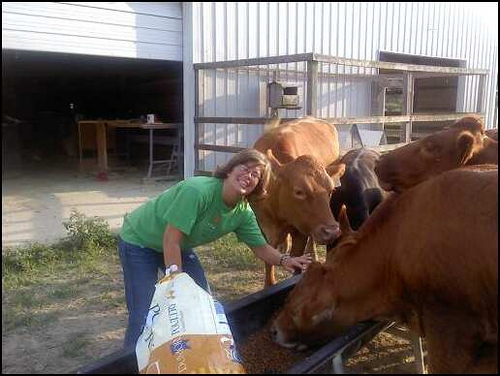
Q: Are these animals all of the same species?
A: Yes, all the animals are cows.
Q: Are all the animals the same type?
A: Yes, all the animals are cows.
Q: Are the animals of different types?
A: No, all the animals are cows.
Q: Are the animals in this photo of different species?
A: No, all the animals are cows.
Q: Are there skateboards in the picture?
A: No, there are no skateboards.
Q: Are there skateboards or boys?
A: No, there are no skateboards or boys.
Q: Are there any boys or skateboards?
A: No, there are no skateboards or boys.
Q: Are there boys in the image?
A: No, there are no boys.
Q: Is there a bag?
A: Yes, there is a bag.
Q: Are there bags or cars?
A: Yes, there is a bag.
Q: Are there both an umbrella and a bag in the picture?
A: No, there is a bag but no umbrellas.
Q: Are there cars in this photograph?
A: No, there are no cars.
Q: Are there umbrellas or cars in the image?
A: No, there are no cars or umbrellas.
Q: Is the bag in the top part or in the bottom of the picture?
A: The bag is in the bottom of the image.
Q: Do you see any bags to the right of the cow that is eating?
A: No, the bag is to the left of the cow.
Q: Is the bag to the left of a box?
A: No, the bag is to the left of the cow.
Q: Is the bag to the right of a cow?
A: No, the bag is to the left of a cow.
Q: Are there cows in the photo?
A: Yes, there is a cow.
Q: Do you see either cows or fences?
A: Yes, there is a cow.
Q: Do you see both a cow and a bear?
A: No, there is a cow but no bears.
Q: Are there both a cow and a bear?
A: No, there is a cow but no bears.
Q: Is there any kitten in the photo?
A: No, there are no kittens.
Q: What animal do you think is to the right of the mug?
A: The animal is a cow.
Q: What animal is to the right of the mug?
A: The animal is a cow.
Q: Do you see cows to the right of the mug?
A: Yes, there is a cow to the right of the mug.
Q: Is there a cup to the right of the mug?
A: No, there is a cow to the right of the mug.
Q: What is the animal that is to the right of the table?
A: The animal is a cow.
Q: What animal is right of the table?
A: The animal is a cow.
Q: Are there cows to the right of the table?
A: Yes, there is a cow to the right of the table.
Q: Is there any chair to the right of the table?
A: No, there is a cow to the right of the table.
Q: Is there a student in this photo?
A: No, there are no students.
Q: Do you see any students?
A: No, there are no students.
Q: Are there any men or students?
A: No, there are no students or men.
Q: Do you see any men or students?
A: No, there are no students or men.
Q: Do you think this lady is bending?
A: Yes, the lady is bending.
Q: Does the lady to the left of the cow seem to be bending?
A: Yes, the lady is bending.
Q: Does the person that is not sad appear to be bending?
A: Yes, the lady is bending.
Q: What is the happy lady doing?
A: The lady is bending.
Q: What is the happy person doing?
A: The lady is bending.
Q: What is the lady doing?
A: The lady is bending.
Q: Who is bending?
A: The lady is bending.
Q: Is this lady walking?
A: No, the lady is bending.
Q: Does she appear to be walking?
A: No, the lady is bending.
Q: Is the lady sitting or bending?
A: The lady is bending.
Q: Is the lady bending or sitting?
A: The lady is bending.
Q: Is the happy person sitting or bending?
A: The lady is bending.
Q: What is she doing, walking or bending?
A: The lady is bending.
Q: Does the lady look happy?
A: Yes, the lady is happy.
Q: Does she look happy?
A: Yes, the lady is happy.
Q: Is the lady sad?
A: No, the lady is happy.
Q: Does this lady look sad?
A: No, the lady is happy.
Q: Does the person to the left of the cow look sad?
A: No, the lady is happy.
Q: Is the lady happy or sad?
A: The lady is happy.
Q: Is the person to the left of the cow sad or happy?
A: The lady is happy.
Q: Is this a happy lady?
A: Yes, this is a happy lady.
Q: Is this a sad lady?
A: No, this is a happy lady.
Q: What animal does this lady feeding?
A: The lady feeding the cow.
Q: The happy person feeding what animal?
A: The lady feeding the cow.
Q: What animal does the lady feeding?
A: The lady feeding the cow.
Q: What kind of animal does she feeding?
A: The lady feeding the cow.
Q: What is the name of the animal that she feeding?
A: The animal is a cow.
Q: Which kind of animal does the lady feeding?
A: The lady feeding the cow.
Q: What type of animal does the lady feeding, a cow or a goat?
A: The lady feeding a cow.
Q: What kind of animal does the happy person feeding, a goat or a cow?
A: The lady feeding a cow.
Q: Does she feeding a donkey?
A: No, the lady feeding the cow.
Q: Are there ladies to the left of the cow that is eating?
A: Yes, there is a lady to the left of the cow.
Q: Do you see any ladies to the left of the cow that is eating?
A: Yes, there is a lady to the left of the cow.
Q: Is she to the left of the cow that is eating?
A: Yes, the lady is to the left of the cow.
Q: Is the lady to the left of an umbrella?
A: No, the lady is to the left of the cow.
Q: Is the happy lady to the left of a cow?
A: Yes, the lady is to the left of a cow.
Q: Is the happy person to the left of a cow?
A: Yes, the lady is to the left of a cow.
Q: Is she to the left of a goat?
A: No, the lady is to the left of a cow.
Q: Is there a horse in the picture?
A: No, there are no horses.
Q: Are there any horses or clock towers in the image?
A: No, there are no horses or clock towers.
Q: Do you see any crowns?
A: No, there are no crowns.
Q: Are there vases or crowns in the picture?
A: No, there are no crowns or vases.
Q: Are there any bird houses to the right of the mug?
A: Yes, there is a bird house to the right of the mug.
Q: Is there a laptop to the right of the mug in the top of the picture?
A: No, there is a bird house to the right of the mug.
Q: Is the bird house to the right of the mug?
A: Yes, the bird house is to the right of the mug.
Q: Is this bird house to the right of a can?
A: No, the bird house is to the right of the mug.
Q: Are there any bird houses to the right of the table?
A: Yes, there is a bird house to the right of the table.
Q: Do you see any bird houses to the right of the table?
A: Yes, there is a bird house to the right of the table.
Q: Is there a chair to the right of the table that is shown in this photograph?
A: No, there is a bird house to the right of the table.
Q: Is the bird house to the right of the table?
A: Yes, the bird house is to the right of the table.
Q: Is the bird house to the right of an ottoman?
A: No, the bird house is to the right of the table.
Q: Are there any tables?
A: Yes, there is a table.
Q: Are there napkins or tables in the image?
A: Yes, there is a table.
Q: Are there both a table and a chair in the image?
A: No, there is a table but no chairs.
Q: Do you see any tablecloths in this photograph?
A: No, there are no tablecloths.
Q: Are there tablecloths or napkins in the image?
A: No, there are no tablecloths or napkins.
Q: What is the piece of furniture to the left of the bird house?
A: The piece of furniture is a table.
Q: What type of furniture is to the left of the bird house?
A: The piece of furniture is a table.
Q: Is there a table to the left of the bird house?
A: Yes, there is a table to the left of the bird house.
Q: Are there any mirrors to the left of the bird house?
A: No, there is a table to the left of the bird house.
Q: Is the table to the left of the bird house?
A: Yes, the table is to the left of the bird house.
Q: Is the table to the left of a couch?
A: No, the table is to the left of the bird house.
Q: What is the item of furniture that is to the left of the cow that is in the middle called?
A: The piece of furniture is a table.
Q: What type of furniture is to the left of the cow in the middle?
A: The piece of furniture is a table.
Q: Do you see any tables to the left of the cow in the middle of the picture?
A: Yes, there is a table to the left of the cow.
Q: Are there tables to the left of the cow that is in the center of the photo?
A: Yes, there is a table to the left of the cow.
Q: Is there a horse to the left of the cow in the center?
A: No, there is a table to the left of the cow.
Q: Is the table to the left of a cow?
A: Yes, the table is to the left of a cow.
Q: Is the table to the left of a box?
A: No, the table is to the left of a cow.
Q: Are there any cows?
A: Yes, there is a cow.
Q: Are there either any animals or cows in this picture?
A: Yes, there is a cow.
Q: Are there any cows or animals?
A: Yes, there is a cow.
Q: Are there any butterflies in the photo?
A: No, there are no butterflies.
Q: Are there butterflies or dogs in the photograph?
A: No, there are no butterflies or dogs.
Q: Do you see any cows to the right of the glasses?
A: Yes, there is a cow to the right of the glasses.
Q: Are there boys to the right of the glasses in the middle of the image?
A: No, there is a cow to the right of the glasses.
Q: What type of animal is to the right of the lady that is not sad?
A: The animal is a cow.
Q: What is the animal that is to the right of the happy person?
A: The animal is a cow.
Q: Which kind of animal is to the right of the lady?
A: The animal is a cow.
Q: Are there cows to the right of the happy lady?
A: Yes, there is a cow to the right of the lady.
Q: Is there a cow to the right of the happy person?
A: Yes, there is a cow to the right of the lady.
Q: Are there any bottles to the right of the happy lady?
A: No, there is a cow to the right of the lady.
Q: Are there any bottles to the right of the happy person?
A: No, there is a cow to the right of the lady.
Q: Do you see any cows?
A: Yes, there is a cow.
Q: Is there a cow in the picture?
A: Yes, there is a cow.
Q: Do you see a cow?
A: Yes, there is a cow.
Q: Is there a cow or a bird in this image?
A: Yes, there is a cow.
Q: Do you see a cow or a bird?
A: Yes, there is a cow.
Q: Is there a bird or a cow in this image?
A: Yes, there is a cow.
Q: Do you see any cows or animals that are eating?
A: Yes, the cow is eating.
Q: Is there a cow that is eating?
A: Yes, there is a cow that is eating.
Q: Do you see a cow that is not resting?
A: Yes, there is a cow that is eating .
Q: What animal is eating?
A: The animal is a cow.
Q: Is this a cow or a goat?
A: This is a cow.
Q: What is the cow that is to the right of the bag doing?
A: The cow is eating.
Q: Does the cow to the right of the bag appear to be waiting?
A: No, the cow is eating.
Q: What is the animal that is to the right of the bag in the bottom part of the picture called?
A: The animal is a cow.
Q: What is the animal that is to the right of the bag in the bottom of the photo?
A: The animal is a cow.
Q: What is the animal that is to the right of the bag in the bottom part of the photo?
A: The animal is a cow.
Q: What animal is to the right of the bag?
A: The animal is a cow.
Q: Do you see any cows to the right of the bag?
A: Yes, there is a cow to the right of the bag.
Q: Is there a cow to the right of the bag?
A: Yes, there is a cow to the right of the bag.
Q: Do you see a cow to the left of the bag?
A: No, the cow is to the right of the bag.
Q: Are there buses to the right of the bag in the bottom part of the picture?
A: No, there is a cow to the right of the bag.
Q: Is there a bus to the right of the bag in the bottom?
A: No, there is a cow to the right of the bag.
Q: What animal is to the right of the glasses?
A: The animal is a cow.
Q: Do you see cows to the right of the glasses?
A: Yes, there is a cow to the right of the glasses.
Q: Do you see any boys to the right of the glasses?
A: No, there is a cow to the right of the glasses.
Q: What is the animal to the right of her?
A: The animal is a cow.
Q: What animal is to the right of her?
A: The animal is a cow.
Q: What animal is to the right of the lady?
A: The animal is a cow.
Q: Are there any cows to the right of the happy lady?
A: Yes, there is a cow to the right of the lady.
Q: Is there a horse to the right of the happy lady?
A: No, there is a cow to the right of the lady.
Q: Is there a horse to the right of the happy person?
A: No, there is a cow to the right of the lady.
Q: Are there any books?
A: No, there are no books.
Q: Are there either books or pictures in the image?
A: No, there are no books or pictures.